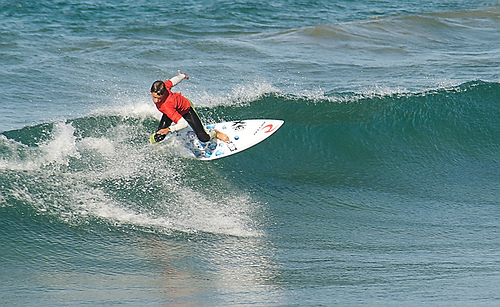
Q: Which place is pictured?
A: It is an ocean.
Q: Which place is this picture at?
A: It is at the ocean.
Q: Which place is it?
A: It is an ocean.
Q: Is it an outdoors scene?
A: Yes, it is outdoors.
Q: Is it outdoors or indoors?
A: It is outdoors.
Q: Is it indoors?
A: No, it is outdoors.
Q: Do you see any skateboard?
A: No, there are no skateboards.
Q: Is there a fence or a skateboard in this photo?
A: No, there are no skateboards or fences.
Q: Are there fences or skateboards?
A: No, there are no skateboards or fences.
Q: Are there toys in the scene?
A: No, there are no toys.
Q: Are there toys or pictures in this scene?
A: No, there are no toys or pictures.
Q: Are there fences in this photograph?
A: No, there are no fences.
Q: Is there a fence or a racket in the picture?
A: No, there are no fences or rackets.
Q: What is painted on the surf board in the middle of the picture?
A: The logo is painted on the surfboard.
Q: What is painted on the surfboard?
A: The logo is painted on the surfboard.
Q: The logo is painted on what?
A: The logo is painted on the surfboard.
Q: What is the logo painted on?
A: The logo is painted on the surfboard.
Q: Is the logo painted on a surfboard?
A: Yes, the logo is painted on a surfboard.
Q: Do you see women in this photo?
A: No, there are no women.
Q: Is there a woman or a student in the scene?
A: No, there are no women or students.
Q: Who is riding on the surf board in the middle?
A: The boy is riding on the surfboard.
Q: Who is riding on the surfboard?
A: The boy is riding on the surfboard.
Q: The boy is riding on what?
A: The boy is riding on the surfboard.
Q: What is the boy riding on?
A: The boy is riding on the surfboard.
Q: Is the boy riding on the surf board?
A: Yes, the boy is riding on the surf board.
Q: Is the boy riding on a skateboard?
A: No, the boy is riding on the surf board.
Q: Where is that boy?
A: The boy is in the ocean.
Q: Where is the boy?
A: The boy is in the ocean.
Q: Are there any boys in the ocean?
A: Yes, there is a boy in the ocean.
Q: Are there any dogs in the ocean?
A: No, there is a boy in the ocean.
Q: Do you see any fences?
A: No, there are no fences.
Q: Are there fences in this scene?
A: No, there are no fences.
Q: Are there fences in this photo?
A: No, there are no fences.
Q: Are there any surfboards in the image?
A: Yes, there is a surfboard.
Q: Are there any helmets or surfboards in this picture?
A: Yes, there is a surfboard.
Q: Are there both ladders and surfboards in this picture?
A: No, there is a surfboard but no ladders.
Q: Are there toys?
A: No, there are no toys.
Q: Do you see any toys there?
A: No, there are no toys.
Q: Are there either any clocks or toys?
A: No, there are no toys or clocks.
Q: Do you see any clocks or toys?
A: No, there are no toys or clocks.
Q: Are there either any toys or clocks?
A: No, there are no toys or clocks.